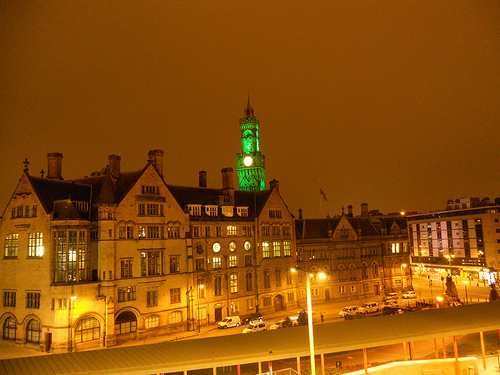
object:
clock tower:
[235, 87, 266, 193]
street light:
[303, 264, 329, 373]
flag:
[315, 188, 331, 204]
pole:
[316, 185, 329, 218]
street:
[0, 272, 499, 359]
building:
[404, 201, 499, 300]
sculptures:
[18, 156, 42, 181]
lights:
[212, 240, 220, 253]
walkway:
[0, 277, 488, 364]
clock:
[240, 154, 257, 167]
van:
[216, 313, 242, 330]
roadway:
[0, 288, 462, 360]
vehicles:
[336, 304, 360, 318]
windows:
[228, 238, 240, 250]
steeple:
[235, 109, 259, 154]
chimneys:
[43, 151, 64, 182]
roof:
[7, 160, 297, 221]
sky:
[0, 1, 499, 220]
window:
[29, 247, 37, 258]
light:
[234, 117, 267, 190]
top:
[233, 92, 265, 122]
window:
[112, 310, 133, 323]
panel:
[33, 307, 494, 371]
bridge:
[177, 302, 482, 374]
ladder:
[490, 216, 500, 260]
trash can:
[331, 360, 343, 373]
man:
[316, 310, 324, 320]